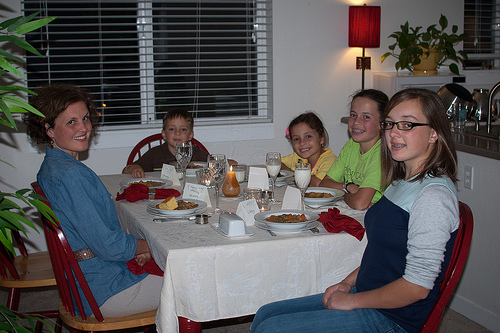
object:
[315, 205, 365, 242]
napkin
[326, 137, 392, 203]
tee shirt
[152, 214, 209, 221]
silverware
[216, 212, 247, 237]
butter plate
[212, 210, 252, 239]
butter dish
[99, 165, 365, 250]
table top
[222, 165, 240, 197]
candle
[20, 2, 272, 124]
gray blinds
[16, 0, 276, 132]
window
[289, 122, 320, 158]
face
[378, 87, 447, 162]
head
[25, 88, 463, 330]
group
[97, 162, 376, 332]
dining table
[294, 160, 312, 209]
glass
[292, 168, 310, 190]
milk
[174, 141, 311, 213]
whole glass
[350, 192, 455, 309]
arm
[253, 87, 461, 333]
person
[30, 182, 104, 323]
chair back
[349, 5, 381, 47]
red lampshade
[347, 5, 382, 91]
lamp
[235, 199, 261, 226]
card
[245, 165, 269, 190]
card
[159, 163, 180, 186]
card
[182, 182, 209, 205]
card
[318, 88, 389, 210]
person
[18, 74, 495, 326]
family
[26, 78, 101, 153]
head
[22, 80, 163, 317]
person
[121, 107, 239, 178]
boy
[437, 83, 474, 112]
pots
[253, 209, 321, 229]
white bowl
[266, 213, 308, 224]
food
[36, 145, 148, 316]
shirt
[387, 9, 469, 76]
plant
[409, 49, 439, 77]
pot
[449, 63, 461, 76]
leaf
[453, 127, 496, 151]
countertop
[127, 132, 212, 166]
chair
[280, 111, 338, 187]
girl